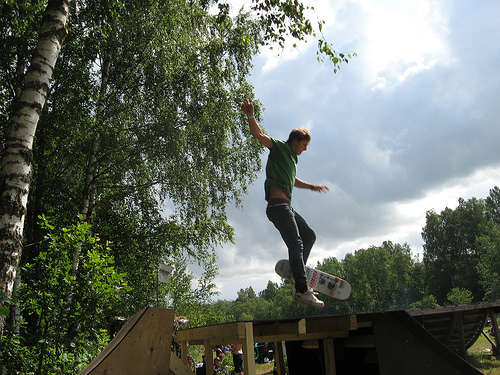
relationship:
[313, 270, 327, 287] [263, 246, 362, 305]
stickers on skateboard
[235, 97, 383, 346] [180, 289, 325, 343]
he on ramp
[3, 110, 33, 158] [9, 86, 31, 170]
moss on tree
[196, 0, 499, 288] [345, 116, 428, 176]
clouds in sky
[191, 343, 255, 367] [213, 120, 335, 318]
people watching skateboarder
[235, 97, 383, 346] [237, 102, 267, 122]
he wearing a watch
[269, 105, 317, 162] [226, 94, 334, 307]
head on man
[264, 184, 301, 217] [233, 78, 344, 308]
belt on man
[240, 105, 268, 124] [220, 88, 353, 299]
watch on man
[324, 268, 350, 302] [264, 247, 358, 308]
wheels on skateboard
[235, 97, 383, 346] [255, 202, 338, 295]
he wearing jeans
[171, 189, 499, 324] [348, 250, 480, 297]
trees with leaves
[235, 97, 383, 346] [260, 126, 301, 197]
he wearing shirt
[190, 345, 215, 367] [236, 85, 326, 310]
spectator watching skateboarder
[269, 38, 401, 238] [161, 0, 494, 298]
clouds in sky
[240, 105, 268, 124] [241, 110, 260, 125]
watch on person's wrist